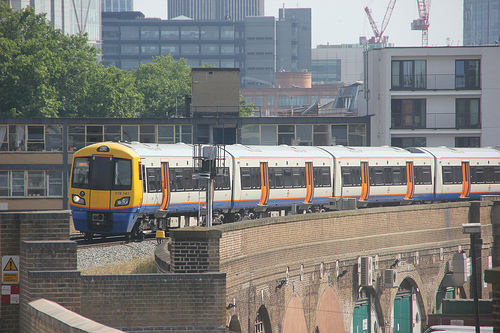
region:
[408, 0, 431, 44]
A large red crane.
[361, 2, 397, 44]
Another red crane.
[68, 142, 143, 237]
Yellow and blue front.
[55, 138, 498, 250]
A train on the tracks.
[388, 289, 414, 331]
A green dutch door.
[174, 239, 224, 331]
A red brick wall.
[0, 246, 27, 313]
Two signs posted on wall.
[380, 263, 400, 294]
Air conditiong on the wall.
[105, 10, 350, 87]
Tall buildings in the distance.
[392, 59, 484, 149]
Large windows for building.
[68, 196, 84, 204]
The left light on the train that is turned on.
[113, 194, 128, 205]
The right side light on the front of the train.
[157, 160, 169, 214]
The orange door closest to the front of the train.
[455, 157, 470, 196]
The last orange door on the train.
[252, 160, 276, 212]
The second orange door on the train.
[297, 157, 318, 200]
The third orange door on the train.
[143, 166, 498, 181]
The passenger windows on the train.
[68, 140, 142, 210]
The yellow paint on the front of the train.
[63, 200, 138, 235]
The blue paint on the front of the train.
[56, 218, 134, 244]
The train tracks the train is driving on.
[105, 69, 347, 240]
A train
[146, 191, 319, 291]
A train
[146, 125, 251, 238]
A train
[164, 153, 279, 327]
A train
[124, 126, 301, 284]
A train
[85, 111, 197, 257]
A train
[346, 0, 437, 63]
construction cranes on roof tops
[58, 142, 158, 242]
Yellow and blue front to train engine car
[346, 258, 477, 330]
arches over closed green doors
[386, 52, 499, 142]
sliding glass doors out to balconies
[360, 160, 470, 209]
roange access doors to train passenger cars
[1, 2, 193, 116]
green treetops rising over buildings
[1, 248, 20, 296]
a caution sign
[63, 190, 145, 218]
train headlights with only one working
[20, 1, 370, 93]
tall buildings in the background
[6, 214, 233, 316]
brick wall of raised railway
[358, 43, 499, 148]
The building is tall.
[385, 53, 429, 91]
The balcony has sliding glass doors.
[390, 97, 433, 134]
The balcony has a railing.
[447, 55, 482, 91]
The railing is black.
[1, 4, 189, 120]
The trees are green.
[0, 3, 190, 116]
The trees are lush.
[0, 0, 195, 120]
The trees are leafy.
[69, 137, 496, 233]
The train is white.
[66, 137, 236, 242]
Front of engine car is yellow.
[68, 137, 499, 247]
The train is long.